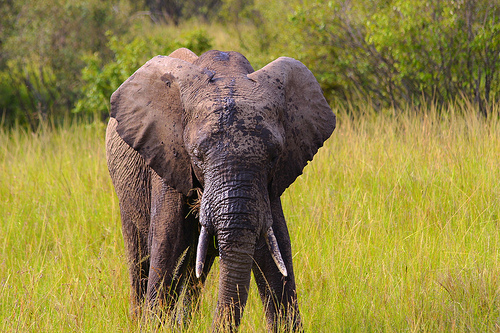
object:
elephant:
[90, 32, 351, 333]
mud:
[225, 100, 237, 111]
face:
[178, 88, 295, 333]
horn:
[257, 223, 296, 279]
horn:
[190, 223, 212, 280]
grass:
[309, 284, 495, 332]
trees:
[0, 38, 36, 133]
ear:
[256, 48, 345, 200]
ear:
[101, 53, 190, 200]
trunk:
[204, 170, 267, 333]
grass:
[4, 165, 102, 333]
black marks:
[272, 253, 278, 257]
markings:
[210, 85, 224, 95]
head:
[106, 56, 338, 333]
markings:
[221, 52, 230, 60]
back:
[153, 44, 252, 76]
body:
[102, 47, 250, 227]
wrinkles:
[124, 149, 135, 162]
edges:
[152, 169, 169, 185]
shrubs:
[449, 0, 491, 116]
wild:
[0, 0, 500, 333]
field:
[0, 113, 497, 332]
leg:
[252, 196, 305, 333]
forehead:
[187, 92, 281, 139]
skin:
[93, 45, 336, 332]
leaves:
[117, 42, 138, 54]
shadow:
[180, 220, 196, 244]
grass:
[329, 133, 479, 222]